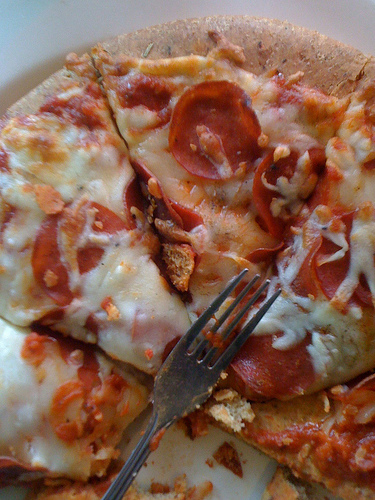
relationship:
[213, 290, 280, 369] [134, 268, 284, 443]
part of a fork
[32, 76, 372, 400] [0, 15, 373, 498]
pepperoni on pizza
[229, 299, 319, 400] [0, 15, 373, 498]
pepperoni on pizza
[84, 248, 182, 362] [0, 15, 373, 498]
cheese on pizza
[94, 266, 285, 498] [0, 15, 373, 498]
fork on pizza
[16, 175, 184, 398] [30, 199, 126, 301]
melted cheese and pepperoni